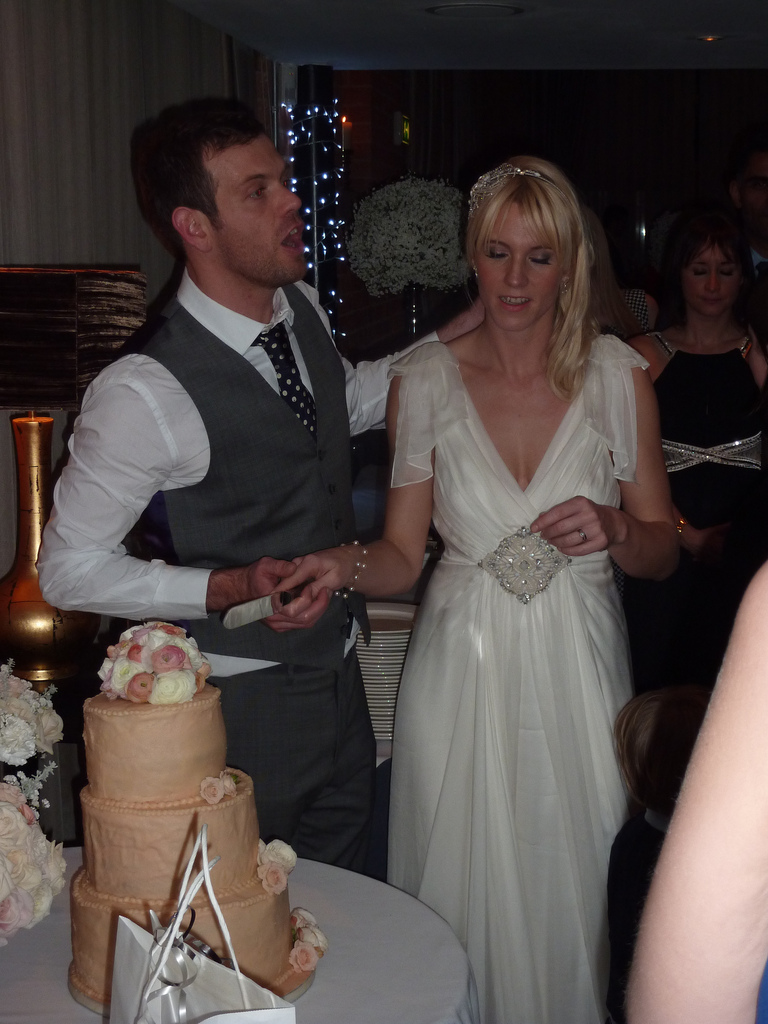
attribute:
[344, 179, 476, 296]
bush — decorative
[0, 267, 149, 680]
lamp — brown and gold